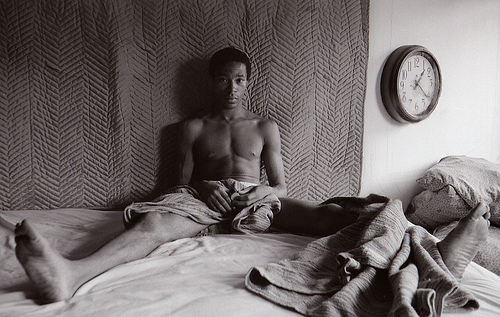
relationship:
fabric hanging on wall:
[0, 1, 369, 212] [0, 1, 499, 215]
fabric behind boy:
[0, 1, 369, 212] [13, 45, 363, 305]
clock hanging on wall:
[378, 45, 441, 128] [0, 1, 499, 215]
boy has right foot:
[13, 45, 363, 305] [15, 215, 72, 305]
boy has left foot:
[13, 45, 363, 305] [435, 201, 492, 280]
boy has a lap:
[13, 45, 363, 305] [181, 181, 280, 234]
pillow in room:
[415, 154, 499, 218] [2, 2, 499, 316]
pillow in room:
[406, 186, 476, 228] [2, 2, 499, 316]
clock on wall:
[378, 45, 441, 128] [0, 1, 499, 215]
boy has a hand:
[13, 45, 363, 305] [230, 184, 273, 210]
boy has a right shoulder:
[13, 45, 363, 305] [174, 109, 215, 149]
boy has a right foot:
[13, 45, 363, 305] [15, 215, 72, 305]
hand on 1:
[411, 68, 426, 91] [421, 56, 426, 69]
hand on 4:
[413, 79, 430, 100] [426, 90, 431, 102]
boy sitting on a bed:
[13, 45, 363, 305] [3, 208, 498, 316]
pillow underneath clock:
[415, 154, 499, 218] [378, 45, 441, 128]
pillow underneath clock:
[406, 186, 476, 228] [378, 45, 441, 128]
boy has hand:
[13, 45, 363, 305] [230, 184, 273, 210]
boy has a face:
[13, 45, 363, 305] [215, 58, 245, 111]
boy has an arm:
[13, 45, 363, 305] [264, 141, 288, 200]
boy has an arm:
[13, 45, 363, 305] [172, 134, 195, 187]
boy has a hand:
[13, 45, 363, 305] [198, 178, 236, 218]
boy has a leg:
[13, 45, 363, 305] [71, 207, 209, 292]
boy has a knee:
[13, 45, 363, 305] [139, 209, 169, 243]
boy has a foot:
[13, 45, 363, 305] [435, 200, 492, 280]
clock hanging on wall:
[378, 45, 441, 128] [357, 1, 499, 211]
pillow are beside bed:
[406, 186, 476, 228] [3, 208, 498, 316]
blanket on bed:
[243, 190, 479, 317] [3, 208, 498, 316]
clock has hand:
[378, 45, 441, 128] [413, 79, 430, 100]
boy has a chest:
[13, 45, 363, 305] [198, 126, 262, 169]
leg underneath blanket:
[272, 194, 360, 237] [243, 190, 479, 317]